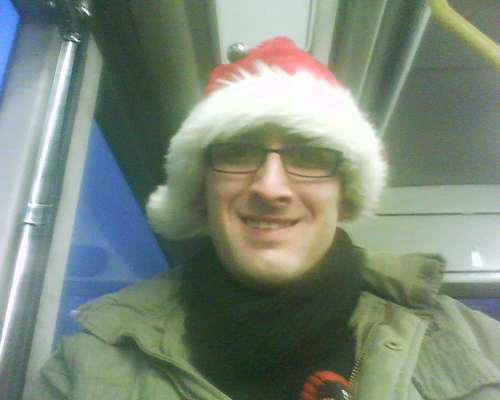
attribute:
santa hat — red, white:
[144, 36, 388, 240]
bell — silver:
[226, 41, 249, 64]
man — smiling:
[35, 36, 499, 399]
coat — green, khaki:
[23, 245, 499, 399]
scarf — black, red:
[178, 227, 366, 399]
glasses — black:
[204, 140, 346, 179]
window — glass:
[52, 117, 174, 355]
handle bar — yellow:
[426, 0, 499, 70]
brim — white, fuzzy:
[164, 61, 389, 226]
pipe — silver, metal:
[0, 34, 66, 398]